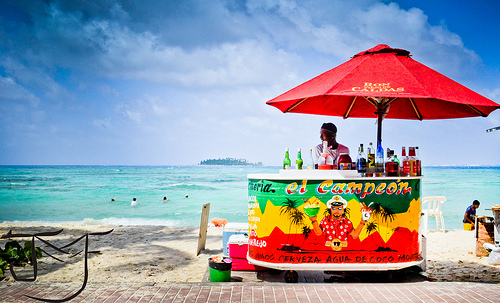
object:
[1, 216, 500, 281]
beach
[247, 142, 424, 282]
beach bar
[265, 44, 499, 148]
umbrella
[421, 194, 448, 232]
chair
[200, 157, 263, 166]
island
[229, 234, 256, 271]
cooler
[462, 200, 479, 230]
man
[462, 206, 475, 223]
shirt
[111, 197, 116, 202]
swimmer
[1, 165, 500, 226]
water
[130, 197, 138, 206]
swimmer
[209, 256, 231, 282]
trash can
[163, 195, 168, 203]
swimmer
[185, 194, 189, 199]
swimmer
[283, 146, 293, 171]
bottles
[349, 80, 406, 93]
logo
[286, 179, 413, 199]
company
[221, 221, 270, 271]
supplies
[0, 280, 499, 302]
walkway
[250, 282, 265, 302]
bricks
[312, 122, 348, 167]
man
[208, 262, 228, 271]
black liner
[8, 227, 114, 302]
jf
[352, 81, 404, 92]
writing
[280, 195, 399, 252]
picture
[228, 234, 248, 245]
lid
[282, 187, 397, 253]
design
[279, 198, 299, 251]
trees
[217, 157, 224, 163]
trees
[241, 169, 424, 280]
bar